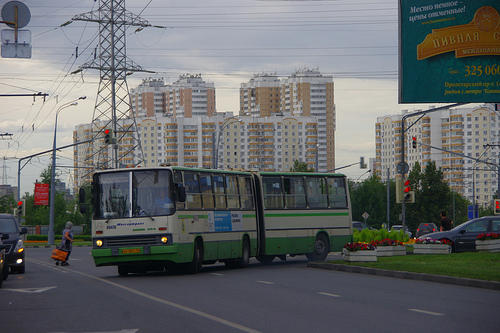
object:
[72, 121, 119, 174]
building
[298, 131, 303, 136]
window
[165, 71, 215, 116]
building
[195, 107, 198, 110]
window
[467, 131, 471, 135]
window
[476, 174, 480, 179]
window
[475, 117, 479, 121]
window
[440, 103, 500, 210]
building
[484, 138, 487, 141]
window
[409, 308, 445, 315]
line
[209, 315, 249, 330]
line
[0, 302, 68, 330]
pavement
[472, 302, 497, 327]
pavement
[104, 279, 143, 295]
line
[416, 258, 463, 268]
grass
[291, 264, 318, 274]
street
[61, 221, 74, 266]
person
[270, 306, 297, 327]
road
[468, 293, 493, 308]
road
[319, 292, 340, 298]
lines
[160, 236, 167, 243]
headlight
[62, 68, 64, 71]
power lines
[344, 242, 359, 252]
flowers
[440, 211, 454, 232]
man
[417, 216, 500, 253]
car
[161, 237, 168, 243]
light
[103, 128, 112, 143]
traffic light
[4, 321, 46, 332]
street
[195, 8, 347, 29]
clouds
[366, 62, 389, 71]
sky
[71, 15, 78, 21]
power lines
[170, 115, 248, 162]
buildings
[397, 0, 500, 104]
billboard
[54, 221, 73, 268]
human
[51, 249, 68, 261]
something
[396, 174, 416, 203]
traffic light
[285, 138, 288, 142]
window on side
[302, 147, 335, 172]
side of building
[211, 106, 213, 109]
window on side of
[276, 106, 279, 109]
window on side of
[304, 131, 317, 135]
window on side of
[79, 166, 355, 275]
"white and green bus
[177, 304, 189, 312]
line on the pavement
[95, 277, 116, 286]
white line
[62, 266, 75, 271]
line on the pavement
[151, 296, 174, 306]
line on the pavement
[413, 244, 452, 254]
white flower pot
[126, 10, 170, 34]
power lines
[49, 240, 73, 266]
human tows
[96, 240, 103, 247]
bus headlights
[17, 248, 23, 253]
vehicle headlights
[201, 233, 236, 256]
green and white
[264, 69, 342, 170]
buildings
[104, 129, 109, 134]
traffic light is red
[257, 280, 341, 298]
white dashed lines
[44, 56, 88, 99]
power lines above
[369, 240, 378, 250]
flowers are red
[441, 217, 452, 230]
black shirt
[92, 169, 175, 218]
he windshield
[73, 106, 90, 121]
clouds in the sky